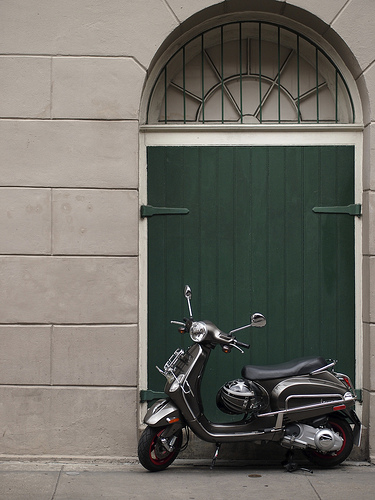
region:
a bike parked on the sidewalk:
[88, 261, 372, 471]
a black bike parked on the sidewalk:
[92, 265, 373, 483]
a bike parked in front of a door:
[69, 231, 372, 493]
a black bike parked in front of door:
[73, 280, 373, 497]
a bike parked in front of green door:
[67, 170, 372, 473]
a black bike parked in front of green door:
[76, 162, 373, 486]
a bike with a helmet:
[91, 248, 351, 468]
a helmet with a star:
[212, 362, 278, 420]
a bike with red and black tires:
[71, 286, 372, 496]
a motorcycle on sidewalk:
[57, 243, 361, 496]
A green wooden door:
[144, 145, 366, 438]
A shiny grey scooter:
[124, 275, 367, 481]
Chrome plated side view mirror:
[219, 311, 273, 342]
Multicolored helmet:
[212, 373, 277, 424]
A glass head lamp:
[186, 317, 210, 344]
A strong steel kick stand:
[199, 432, 239, 479]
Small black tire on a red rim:
[129, 406, 193, 475]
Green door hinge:
[132, 201, 192, 228]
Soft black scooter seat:
[242, 355, 338, 379]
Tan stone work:
[13, 251, 142, 338]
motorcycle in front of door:
[128, 305, 333, 454]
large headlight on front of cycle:
[185, 319, 205, 350]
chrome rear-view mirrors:
[178, 268, 267, 347]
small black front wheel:
[134, 409, 184, 470]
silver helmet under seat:
[194, 348, 324, 417]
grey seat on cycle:
[229, 335, 364, 383]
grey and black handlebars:
[168, 314, 251, 365]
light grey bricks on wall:
[20, 256, 106, 455]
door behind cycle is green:
[151, 171, 319, 337]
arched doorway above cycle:
[138, 19, 369, 114]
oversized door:
[164, 144, 363, 308]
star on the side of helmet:
[212, 365, 259, 393]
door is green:
[209, 195, 337, 317]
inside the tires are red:
[150, 417, 193, 476]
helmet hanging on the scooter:
[215, 372, 265, 426]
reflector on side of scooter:
[314, 398, 365, 424]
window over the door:
[139, 23, 327, 136]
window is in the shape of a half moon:
[161, 66, 369, 134]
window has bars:
[190, 32, 371, 139]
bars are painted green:
[188, 56, 348, 123]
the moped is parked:
[138, 276, 368, 469]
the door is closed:
[139, 137, 372, 491]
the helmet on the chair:
[217, 353, 268, 462]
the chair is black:
[238, 354, 346, 393]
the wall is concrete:
[29, 106, 139, 482]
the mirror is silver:
[162, 270, 290, 391]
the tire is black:
[121, 398, 179, 486]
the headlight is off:
[172, 313, 255, 361]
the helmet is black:
[218, 374, 260, 419]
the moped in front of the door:
[127, 242, 368, 497]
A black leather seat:
[234, 347, 335, 390]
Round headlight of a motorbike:
[182, 315, 209, 349]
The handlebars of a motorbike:
[161, 307, 253, 358]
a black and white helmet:
[214, 378, 259, 415]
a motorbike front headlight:
[189, 320, 206, 341]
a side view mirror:
[249, 312, 268, 328]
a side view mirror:
[182, 283, 191, 301]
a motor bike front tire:
[137, 423, 182, 469]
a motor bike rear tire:
[303, 410, 352, 466]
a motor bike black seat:
[242, 356, 322, 376]